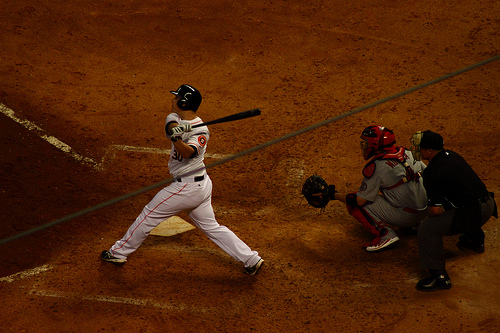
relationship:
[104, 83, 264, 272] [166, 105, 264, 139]
batter has a bat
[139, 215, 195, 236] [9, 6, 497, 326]
home plate on field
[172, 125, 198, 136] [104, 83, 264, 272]
glove of batter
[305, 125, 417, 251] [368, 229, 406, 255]
catcher's has shoes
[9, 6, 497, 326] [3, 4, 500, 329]
ground in picture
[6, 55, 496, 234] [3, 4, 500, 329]
wire in picture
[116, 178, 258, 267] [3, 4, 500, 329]
trouser in picture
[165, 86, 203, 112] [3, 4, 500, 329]
cap in picture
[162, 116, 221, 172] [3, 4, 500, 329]
top in picture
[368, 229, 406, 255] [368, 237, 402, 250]
shoe has a sole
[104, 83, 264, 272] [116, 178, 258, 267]
batter's in uniform pants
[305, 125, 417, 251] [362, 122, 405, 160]
catcher's has helmet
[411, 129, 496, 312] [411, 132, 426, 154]
umpire has a mask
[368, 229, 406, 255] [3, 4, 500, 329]
shoes in picture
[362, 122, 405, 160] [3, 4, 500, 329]
helmet in picture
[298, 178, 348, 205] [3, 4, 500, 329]
glove in picture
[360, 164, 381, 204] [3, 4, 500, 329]
sleeve in picture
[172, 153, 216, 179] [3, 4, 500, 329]
batters waist in picture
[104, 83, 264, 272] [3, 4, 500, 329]
man in picture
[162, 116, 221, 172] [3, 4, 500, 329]
t shirt in picture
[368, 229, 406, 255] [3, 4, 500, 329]
shoe in picture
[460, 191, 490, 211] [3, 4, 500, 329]
belt in picture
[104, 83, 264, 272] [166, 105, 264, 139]
batter swinging baseball bat